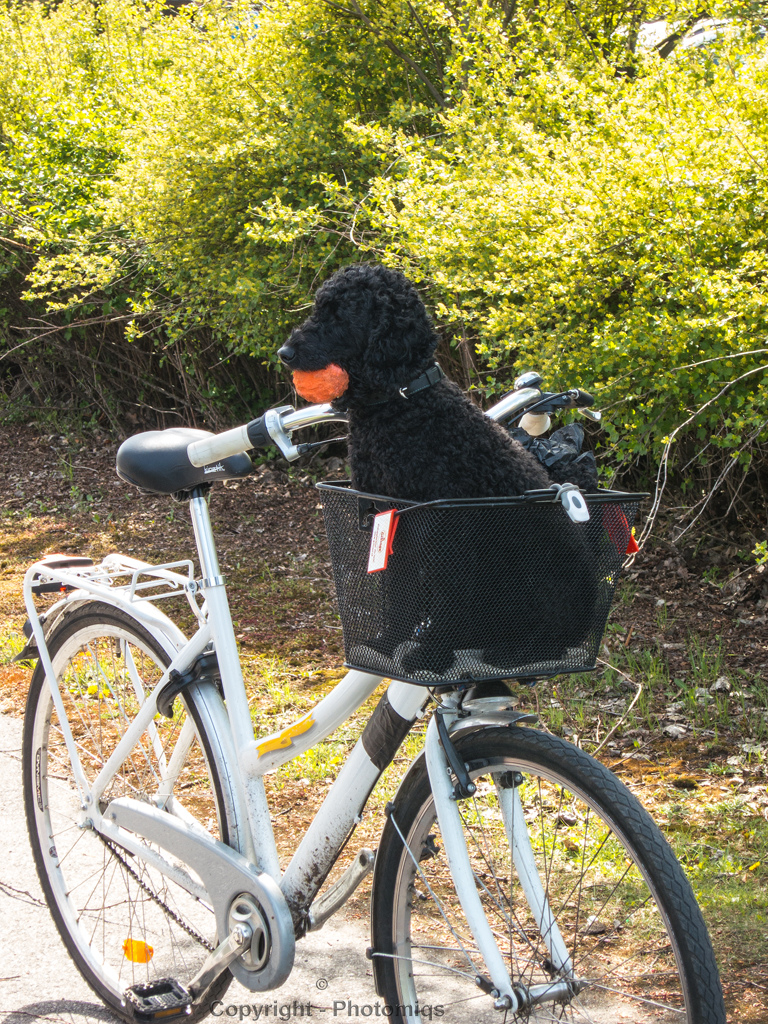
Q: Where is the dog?
A: In the bike basket.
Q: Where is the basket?
A: Front of bike.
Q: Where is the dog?
A: Basket.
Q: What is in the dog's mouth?
A: Ball.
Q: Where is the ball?
A: Dog's mouth.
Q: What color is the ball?
A: Orange.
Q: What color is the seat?
A: Black.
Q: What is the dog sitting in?
A: Basket.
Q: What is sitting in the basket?
A: Dog.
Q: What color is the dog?
A: Black.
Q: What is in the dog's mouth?
A: Ball.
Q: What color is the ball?
A: Orange.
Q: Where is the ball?
A: Dog's mouth.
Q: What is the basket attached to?
A: Bicycle.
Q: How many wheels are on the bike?
A: Two.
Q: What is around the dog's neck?
A: Collar.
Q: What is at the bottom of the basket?
A: Blanket.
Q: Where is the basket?
A: Front of bike.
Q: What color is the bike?
A: White.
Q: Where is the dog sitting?
A: Basket.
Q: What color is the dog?
A: Black.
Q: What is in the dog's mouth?
A: Ball.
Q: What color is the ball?
A: Orange.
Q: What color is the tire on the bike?
A: Black.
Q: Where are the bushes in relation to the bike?
A: Behind.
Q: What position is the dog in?
A: Sitting.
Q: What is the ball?
A: Pink.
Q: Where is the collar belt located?
A: On neck.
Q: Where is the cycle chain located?
A: On wheel.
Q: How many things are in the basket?
A: 3.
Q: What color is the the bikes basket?
A: Black.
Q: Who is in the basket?
A: A black furry dog.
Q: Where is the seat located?
A: On top of the bike.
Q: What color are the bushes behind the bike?
A: Green.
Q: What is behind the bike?
A: Trees.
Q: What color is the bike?
A: White.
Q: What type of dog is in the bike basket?
A: Poodle.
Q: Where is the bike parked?
A: Pavement.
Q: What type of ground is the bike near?
A: Grass.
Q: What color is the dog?
A: Black.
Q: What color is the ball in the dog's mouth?
A: Orange.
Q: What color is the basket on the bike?
A: Black.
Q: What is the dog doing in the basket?
A: Sitting.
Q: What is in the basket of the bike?
A: A black dog.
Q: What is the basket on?
A: A bike.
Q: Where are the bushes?
A: Behind the bike.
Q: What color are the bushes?
A: Green.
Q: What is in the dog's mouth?
A: A ball.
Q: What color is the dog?
A: Black.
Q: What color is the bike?
A: White.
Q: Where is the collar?
A: Dog's neck.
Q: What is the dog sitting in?
A: Bicycle basket.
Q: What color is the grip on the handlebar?
A: White.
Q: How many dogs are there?
A: 1.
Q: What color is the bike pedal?
A: Black.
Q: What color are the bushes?
A: Green.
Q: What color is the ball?
A: Orange.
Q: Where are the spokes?
A: Inside of the tire.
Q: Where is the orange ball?
A: In the dog's mouth.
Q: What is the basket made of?
A: Wire.